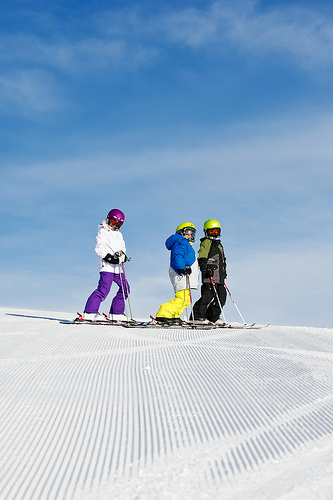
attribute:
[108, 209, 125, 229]
helmet — purple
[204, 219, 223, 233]
helmet — green, yellow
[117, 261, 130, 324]
rod — long, slim, white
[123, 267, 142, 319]
rod — slim, long, white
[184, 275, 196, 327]
rod — slim, long, white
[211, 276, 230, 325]
rod — slim, long, white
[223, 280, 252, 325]
rod — slim, long, white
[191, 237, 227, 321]
suit — beautiful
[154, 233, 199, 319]
suit — beautiful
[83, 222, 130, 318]
suit — beautiful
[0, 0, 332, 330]
sky — blue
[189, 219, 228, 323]
man — standing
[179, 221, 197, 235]
helmet — yellow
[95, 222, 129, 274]
jacket — white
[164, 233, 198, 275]
jacket — blue, white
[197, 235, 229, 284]
jacket — black green gray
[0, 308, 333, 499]
snow — white, packed, crisp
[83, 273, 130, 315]
pants — purple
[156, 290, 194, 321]
pants — yellow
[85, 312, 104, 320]
boot — white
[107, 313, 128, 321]
boot — white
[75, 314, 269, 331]
skis — red black, white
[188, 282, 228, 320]
pants — black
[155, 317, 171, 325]
boot — black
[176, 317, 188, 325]
boot — black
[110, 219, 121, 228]
eye wear — protective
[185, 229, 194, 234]
eye wear — protective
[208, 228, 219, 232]
eye wear — protective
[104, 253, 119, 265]
hand — black, gloved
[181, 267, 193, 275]
hand — black, gloved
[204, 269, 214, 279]
hand — black, gloved